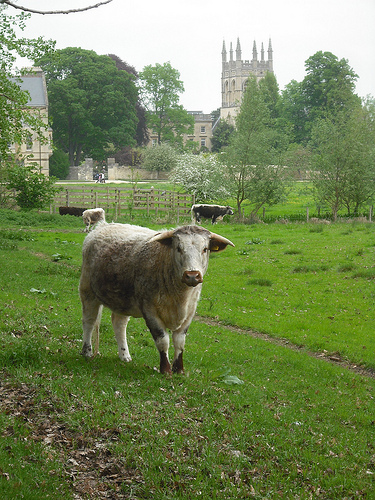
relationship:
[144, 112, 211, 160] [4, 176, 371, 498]
building across field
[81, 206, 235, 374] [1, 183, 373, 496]
cow in pasture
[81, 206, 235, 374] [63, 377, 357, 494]
cow in a pasture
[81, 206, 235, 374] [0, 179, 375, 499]
cow in a field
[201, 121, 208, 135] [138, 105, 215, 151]
window in building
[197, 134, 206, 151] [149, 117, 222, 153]
window in building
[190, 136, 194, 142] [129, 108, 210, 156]
window in building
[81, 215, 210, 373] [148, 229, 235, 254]
cow with horns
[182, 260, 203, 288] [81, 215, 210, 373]
nose on cow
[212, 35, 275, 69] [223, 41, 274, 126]
spires on tower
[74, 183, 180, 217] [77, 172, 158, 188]
fence on road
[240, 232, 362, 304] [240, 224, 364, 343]
tufts in pasture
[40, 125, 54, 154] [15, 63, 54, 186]
window on building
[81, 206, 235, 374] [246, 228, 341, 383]
cow in field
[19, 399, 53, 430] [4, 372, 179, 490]
leaves on ground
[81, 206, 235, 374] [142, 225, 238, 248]
cow has horns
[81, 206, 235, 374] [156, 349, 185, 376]
cow has feet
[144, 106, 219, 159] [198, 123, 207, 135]
building has window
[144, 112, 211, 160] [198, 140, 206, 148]
building has window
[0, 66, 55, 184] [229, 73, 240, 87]
building has window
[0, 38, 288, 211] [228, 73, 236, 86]
building has window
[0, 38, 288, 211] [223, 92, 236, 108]
building has window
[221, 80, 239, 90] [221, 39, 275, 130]
openings on tower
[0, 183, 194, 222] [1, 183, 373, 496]
fence edging pasture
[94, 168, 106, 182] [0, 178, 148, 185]
people walk along road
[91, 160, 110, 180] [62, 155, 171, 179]
entry on wall